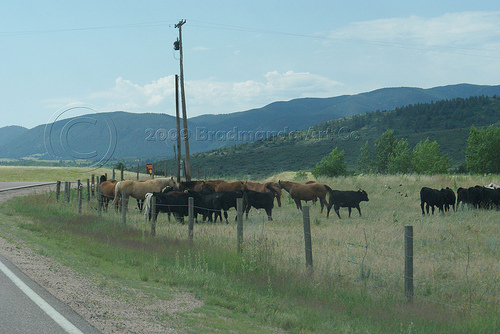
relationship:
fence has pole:
[54, 158, 497, 330] [402, 224, 414, 305]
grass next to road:
[1, 166, 498, 333] [1, 180, 102, 333]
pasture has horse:
[1, 166, 498, 333] [98, 174, 327, 197]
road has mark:
[1, 180, 102, 333] [1, 260, 80, 333]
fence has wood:
[54, 158, 497, 330] [300, 204, 319, 278]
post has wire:
[170, 19, 193, 183] [2, 17, 496, 64]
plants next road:
[144, 231, 291, 322] [1, 180, 102, 333]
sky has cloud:
[1, 1, 498, 129] [43, 69, 355, 120]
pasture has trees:
[89, 167, 497, 311] [293, 122, 499, 177]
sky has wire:
[1, 1, 498, 129] [2, 17, 496, 64]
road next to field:
[1, 180, 102, 333] [54, 158, 497, 330]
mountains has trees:
[0, 83, 499, 162] [132, 95, 497, 173]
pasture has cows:
[89, 167, 497, 311] [420, 183, 499, 214]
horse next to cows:
[98, 174, 327, 197] [420, 183, 499, 214]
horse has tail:
[98, 174, 327, 197] [110, 181, 122, 209]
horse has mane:
[98, 174, 327, 197] [151, 176, 176, 183]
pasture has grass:
[89, 167, 497, 311] [1, 166, 498, 333]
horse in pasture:
[98, 174, 327, 197] [89, 167, 497, 311]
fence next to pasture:
[54, 158, 497, 330] [89, 167, 497, 311]